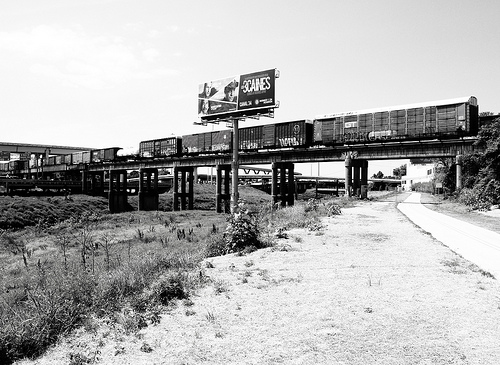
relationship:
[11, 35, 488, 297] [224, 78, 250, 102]
photo in black and white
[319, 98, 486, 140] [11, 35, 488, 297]
train car in photo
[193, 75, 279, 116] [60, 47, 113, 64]
billboard in air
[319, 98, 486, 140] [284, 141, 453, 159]
train car on bridge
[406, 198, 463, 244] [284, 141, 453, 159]
road under bridge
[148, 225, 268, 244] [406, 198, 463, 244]
grass near road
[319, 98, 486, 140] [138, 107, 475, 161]
train car in a row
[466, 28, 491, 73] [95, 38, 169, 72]
clouds in sky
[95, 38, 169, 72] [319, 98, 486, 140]
sky over train car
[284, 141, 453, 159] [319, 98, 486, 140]
bridge paste train car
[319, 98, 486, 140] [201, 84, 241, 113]
train car not for people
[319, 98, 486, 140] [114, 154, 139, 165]
train car on tracks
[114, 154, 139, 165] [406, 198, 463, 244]
tracks passover road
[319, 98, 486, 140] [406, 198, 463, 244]
train car passover road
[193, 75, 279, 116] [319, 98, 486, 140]
billboard over train car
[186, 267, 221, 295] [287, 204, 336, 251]
dirt and weeds on ground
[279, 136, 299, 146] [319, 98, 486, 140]
graffiti on train car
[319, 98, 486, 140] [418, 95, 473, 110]
train car with white roof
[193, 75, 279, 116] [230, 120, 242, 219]
billboard on a pole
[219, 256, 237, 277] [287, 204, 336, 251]
sand on ground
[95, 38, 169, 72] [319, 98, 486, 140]
sky that clear over train car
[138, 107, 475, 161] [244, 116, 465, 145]
row of train cars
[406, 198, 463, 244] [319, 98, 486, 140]
road by train car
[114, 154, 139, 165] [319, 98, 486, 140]
tracks on bottom for th train car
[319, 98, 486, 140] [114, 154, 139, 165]
train car that carry cargo on tracks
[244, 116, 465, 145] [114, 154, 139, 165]
train cars that carry cargo on tracks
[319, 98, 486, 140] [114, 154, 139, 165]
train car that carrys cargo on tracks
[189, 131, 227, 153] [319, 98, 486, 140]
cargo carried by a train car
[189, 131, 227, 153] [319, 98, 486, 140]
cargo carried by train car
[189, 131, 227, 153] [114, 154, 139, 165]
cargo carried on tracks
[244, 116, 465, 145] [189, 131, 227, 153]
train cars that carry cargo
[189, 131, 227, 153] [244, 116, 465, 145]
cargo carried by train cars